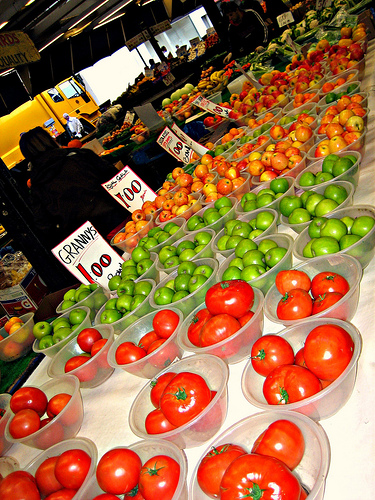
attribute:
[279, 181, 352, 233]
bowl — clear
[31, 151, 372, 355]
grannys — 1.00 per pound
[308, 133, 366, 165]
bowl — clear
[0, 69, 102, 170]
truck — yellow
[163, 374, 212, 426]
tomato — red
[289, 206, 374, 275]
bowl — clear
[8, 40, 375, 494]
table — white, long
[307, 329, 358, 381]
tomato — red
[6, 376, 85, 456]
container — plastic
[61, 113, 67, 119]
cap — white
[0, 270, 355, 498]
tomatoes — for sale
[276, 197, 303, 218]
apple — green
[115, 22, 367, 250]
apples — for sale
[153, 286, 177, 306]
apple — granny smith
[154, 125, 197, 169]
sign — white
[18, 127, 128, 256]
customer — shopping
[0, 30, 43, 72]
sign — hanging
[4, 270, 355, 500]
fruit — red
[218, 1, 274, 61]
person — looking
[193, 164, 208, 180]
apple — red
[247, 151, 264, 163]
apple — yellow